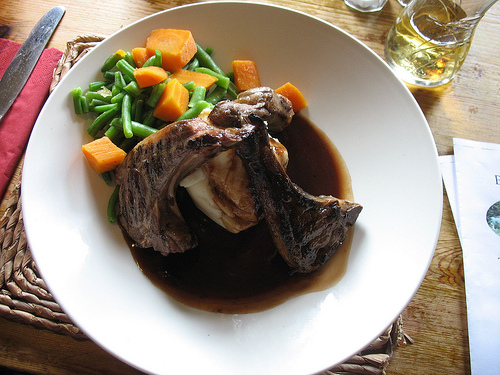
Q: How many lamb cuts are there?
A: Two.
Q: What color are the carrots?
A: Orange.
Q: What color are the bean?
A: Green.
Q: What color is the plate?
A: White.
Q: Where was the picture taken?
A: The restaurant.